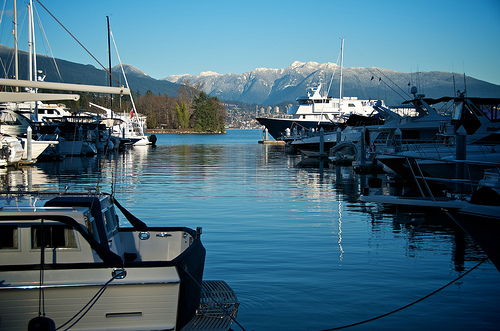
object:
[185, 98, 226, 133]
trees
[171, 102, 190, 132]
trees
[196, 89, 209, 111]
trees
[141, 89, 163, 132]
trees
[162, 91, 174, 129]
trees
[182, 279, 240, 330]
deck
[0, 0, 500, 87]
sky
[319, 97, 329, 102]
window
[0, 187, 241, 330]
boat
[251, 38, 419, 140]
boat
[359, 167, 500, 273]
boat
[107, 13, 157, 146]
boat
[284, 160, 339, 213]
reflection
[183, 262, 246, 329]
rope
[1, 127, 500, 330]
water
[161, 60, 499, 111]
mountains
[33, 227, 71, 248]
window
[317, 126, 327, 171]
posts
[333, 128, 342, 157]
posts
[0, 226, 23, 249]
window